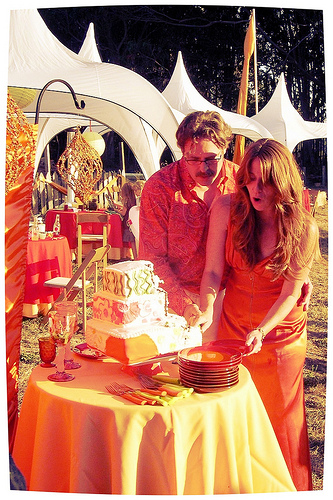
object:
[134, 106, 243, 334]
man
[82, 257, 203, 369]
cake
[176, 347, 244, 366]
plates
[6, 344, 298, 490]
table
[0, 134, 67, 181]
decor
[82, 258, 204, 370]
wedding cake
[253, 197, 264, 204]
mouth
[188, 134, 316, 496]
woman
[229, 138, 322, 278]
hair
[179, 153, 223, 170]
glasses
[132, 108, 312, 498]
couple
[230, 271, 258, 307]
orange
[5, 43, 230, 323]
reception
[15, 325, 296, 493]
tablecloth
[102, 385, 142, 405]
forks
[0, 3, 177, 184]
tents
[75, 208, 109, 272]
chair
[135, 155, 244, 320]
shirt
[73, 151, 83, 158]
glitter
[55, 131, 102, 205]
chandalier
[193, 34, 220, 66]
forest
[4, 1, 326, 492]
scene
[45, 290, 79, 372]
goblet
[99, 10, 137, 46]
trees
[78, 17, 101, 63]
points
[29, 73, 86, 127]
hook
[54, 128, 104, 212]
structure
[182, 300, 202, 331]
hands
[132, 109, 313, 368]
people